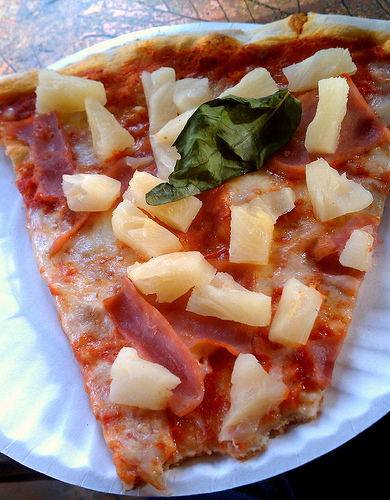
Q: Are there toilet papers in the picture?
A: No, there are no toilet papers.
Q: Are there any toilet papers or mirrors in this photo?
A: No, there are no toilet papers or mirrors.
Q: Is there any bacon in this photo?
A: Yes, there is bacon.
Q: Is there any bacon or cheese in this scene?
A: Yes, there is bacon.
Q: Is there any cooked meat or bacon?
A: Yes, there is cooked bacon.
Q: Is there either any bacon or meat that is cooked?
A: Yes, the bacon is cooked.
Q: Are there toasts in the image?
A: No, there are no toasts.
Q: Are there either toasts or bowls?
A: No, there are no toasts or bowls.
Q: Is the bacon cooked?
A: Yes, the bacon is cooked.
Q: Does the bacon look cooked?
A: Yes, the bacon is cooked.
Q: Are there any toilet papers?
A: No, there are no toilet papers.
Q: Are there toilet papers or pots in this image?
A: No, there are no toilet papers or pots.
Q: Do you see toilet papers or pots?
A: No, there are no toilet papers or pots.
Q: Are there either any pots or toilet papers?
A: No, there are no toilet papers or pots.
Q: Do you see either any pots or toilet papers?
A: No, there are no toilet papers or pots.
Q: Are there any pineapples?
A: Yes, there is a pineapple.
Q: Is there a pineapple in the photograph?
A: Yes, there is a pineapple.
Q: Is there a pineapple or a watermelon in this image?
A: Yes, there is a pineapple.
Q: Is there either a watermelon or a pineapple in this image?
A: Yes, there is a pineapple.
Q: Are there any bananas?
A: No, there are no bananas.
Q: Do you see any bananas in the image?
A: No, there are no bananas.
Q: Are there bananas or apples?
A: No, there are no bananas or apples.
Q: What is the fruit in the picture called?
A: The fruit is a pineapple.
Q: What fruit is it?
A: The fruit is a pineapple.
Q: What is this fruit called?
A: That is a pineapple.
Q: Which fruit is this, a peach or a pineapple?
A: That is a pineapple.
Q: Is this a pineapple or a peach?
A: This is a pineapple.